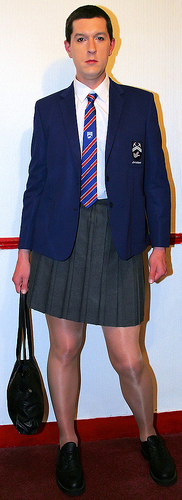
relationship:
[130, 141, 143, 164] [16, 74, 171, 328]
emblem on front of uniform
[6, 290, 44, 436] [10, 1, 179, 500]
bag being held by a man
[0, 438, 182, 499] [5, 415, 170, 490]
carpet on floor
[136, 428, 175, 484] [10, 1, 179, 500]
shoe on a man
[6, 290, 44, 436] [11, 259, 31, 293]
bag in a hand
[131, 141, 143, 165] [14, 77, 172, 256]
emblem on a blazer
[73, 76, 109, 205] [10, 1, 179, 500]
shirt on a man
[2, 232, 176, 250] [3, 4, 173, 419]
strip on wall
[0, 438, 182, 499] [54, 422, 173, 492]
carpet under feet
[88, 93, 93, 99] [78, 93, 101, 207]
stripe on tie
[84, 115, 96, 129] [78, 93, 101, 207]
stripe on tie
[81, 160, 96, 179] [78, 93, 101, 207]
stripe on tie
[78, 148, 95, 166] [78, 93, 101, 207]
stripe on tie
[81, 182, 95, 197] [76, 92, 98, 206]
stripe on tie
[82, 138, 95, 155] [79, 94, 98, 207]
stripe on tie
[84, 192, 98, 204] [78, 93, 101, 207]
stripe on tie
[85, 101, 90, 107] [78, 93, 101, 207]
stripe on tie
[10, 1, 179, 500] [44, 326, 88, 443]
man wearing pantyhose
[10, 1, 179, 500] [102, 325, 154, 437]
man wearing pantyhose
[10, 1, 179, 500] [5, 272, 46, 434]
man carrying a purse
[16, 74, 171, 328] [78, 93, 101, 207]
uniform has tie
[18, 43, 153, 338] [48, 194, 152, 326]
uniform has skirt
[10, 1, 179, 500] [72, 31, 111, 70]
man wearing makeup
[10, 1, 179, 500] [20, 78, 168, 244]
man wearing blazer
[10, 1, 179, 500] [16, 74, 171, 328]
man in uniform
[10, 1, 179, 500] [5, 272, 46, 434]
man holding purse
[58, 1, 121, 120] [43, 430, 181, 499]
man has shoe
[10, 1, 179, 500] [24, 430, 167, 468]
man on carpet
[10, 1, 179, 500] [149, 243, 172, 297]
man has hand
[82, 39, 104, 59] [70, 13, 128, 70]
nose on face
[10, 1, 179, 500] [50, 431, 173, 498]
man has shoe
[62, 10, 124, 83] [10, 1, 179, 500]
head of man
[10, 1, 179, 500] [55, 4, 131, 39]
man has hair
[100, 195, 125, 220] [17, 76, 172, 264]
button on clothing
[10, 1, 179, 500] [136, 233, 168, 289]
man has hand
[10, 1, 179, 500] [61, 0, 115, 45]
man has hair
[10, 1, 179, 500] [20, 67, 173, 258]
man in blazer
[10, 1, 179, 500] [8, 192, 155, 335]
man wearing skirt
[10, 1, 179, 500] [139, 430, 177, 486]
man with shoe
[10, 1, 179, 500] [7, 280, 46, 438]
man with purse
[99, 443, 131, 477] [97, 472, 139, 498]
carpet on floor